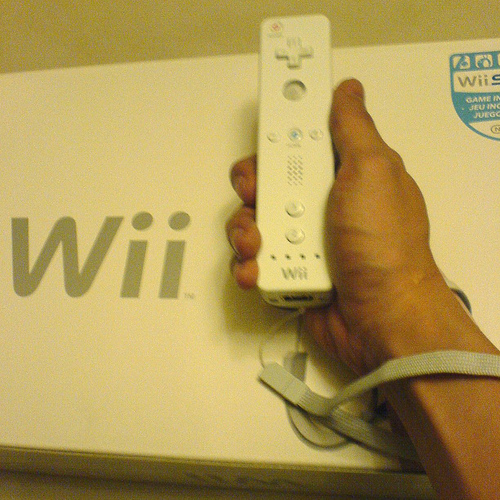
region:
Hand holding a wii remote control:
[217, 4, 498, 496]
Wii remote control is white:
[251, 10, 344, 317]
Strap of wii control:
[254, 296, 498, 472]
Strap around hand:
[249, 277, 499, 470]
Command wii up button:
[281, 33, 306, 45]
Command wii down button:
[285, 56, 305, 68]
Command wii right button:
[298, 41, 313, 59]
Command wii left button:
[272, 42, 287, 59]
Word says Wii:
[7, 194, 204, 322]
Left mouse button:
[280, 76, 313, 107]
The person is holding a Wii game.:
[223, 71, 423, 341]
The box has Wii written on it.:
[8, 175, 201, 331]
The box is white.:
[48, 64, 283, 418]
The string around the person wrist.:
[271, 352, 495, 413]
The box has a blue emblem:
[407, 58, 497, 157]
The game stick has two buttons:
[283, 197, 320, 262]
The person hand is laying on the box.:
[88, 202, 463, 441]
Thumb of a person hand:
[323, 73, 411, 183]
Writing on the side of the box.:
[164, 453, 322, 498]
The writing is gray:
[24, 210, 180, 288]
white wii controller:
[257, 13, 334, 307]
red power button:
[268, 21, 280, 32]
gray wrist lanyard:
[258, 305, 498, 460]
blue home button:
[287, 128, 302, 140]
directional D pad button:
[271, 35, 312, 66]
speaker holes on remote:
[285, 155, 302, 185]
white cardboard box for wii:
[0, 35, 497, 489]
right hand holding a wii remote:
[225, 75, 495, 352]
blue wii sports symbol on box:
[447, 51, 495, 139]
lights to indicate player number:
[267, 252, 322, 263]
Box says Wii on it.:
[23, 163, 212, 379]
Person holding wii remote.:
[229, 225, 416, 338]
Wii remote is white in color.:
[226, 198, 363, 343]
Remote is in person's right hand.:
[228, 145, 398, 317]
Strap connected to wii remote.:
[244, 311, 401, 446]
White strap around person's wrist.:
[263, 326, 496, 438]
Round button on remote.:
[273, 230, 337, 265]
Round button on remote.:
[281, 189, 333, 246]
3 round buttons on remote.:
[258, 122, 395, 187]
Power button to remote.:
[263, 11, 290, 39]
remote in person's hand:
[201, 5, 425, 277]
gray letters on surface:
[1, 219, 213, 339]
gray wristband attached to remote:
[312, 319, 494, 474]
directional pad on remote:
[277, 31, 328, 76]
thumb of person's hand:
[324, 58, 400, 167]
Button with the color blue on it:
[281, 117, 311, 164]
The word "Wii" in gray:
[274, 261, 315, 283]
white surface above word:
[46, 72, 203, 177]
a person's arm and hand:
[143, 106, 495, 482]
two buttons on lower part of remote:
[266, 186, 316, 257]